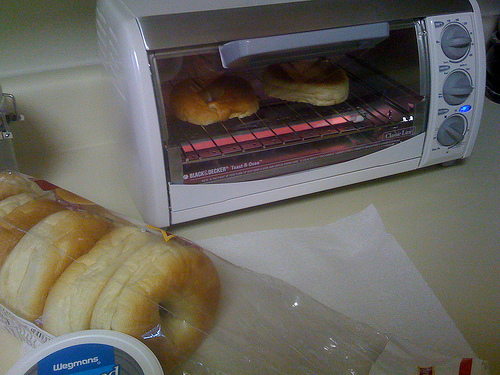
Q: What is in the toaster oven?
A: A bagel.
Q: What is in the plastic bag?
A: Bagels.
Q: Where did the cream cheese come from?
A: Wegman's.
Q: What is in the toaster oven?
A: Bagel.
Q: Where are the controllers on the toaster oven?
A: On the right hand side.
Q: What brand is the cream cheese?
A: Wegmans.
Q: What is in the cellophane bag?
A: Bagels.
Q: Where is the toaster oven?
A: On the counter.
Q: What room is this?
A: Kitchen.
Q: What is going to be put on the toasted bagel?
A: Cream cheese.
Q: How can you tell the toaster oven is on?
A: The light on the bottom is red.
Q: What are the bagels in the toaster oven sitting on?
A: The metal rack.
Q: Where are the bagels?
A: In the toaster oven.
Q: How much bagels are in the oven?
A: One.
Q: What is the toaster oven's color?
A: White.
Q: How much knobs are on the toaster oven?
A: Three.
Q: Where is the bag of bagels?
A: On the counter.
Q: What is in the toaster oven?
A: Bagels.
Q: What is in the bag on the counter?
A: Bagels.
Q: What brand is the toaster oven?
A: Black & Decker.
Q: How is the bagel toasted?
A: Toaster oven.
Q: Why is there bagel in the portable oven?
A: To toast.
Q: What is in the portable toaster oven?
A: Two slices of bagel.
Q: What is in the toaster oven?
A: A bagel.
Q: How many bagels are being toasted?
A: 1.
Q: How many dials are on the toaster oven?
A: 3.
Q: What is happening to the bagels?
A: Being toasted.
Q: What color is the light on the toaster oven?
A: Blue.